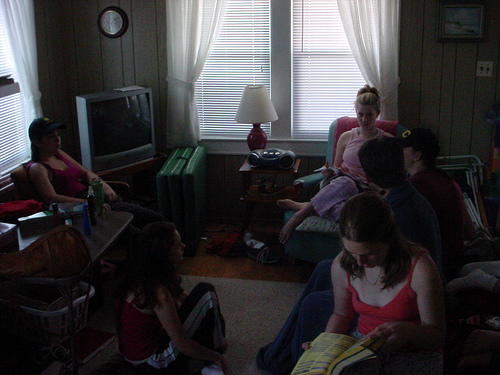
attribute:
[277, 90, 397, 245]
girl — seated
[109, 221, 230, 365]
girl — seated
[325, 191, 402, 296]
head lady — skiing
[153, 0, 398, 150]
curtains — sheer, white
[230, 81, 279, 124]
lamp shade — white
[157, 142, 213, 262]
tables — green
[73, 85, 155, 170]
television — off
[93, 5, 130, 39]
clock — round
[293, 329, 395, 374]
phone book — yellow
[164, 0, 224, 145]
curtain — white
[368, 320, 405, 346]
hand — girl's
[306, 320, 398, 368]
book — yellow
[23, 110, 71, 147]
cap — black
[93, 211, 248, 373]
girl — seated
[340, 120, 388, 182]
shirt — pink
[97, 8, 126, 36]
clock — round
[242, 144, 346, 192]
stereo — black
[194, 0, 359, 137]
blinds — white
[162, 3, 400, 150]
window — white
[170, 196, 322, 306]
floor — hardwood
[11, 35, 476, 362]
people — many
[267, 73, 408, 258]
girl — seated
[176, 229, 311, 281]
floor — wood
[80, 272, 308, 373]
rug — tan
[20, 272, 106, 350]
basket — white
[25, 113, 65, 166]
head — lady's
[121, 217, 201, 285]
head — girl's